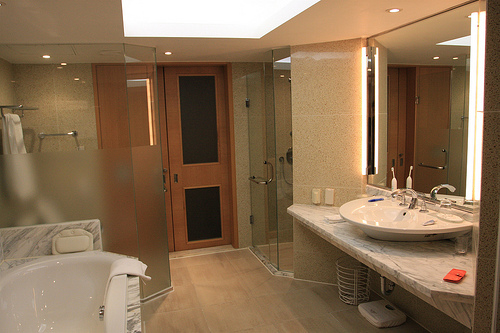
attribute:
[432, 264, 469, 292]
credit card — orange credit card 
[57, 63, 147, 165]
closed glass — CLOSED GLASS SHOWER 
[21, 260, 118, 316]
bathtub — white